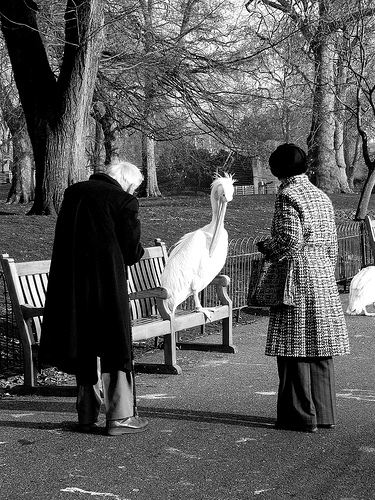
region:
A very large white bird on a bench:
[157, 173, 235, 323]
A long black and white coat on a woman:
[264, 176, 350, 356]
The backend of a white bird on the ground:
[344, 261, 374, 316]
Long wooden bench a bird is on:
[3, 237, 236, 384]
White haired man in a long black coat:
[45, 159, 150, 433]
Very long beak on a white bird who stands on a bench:
[205, 198, 226, 255]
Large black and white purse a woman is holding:
[247, 253, 298, 310]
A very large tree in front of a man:
[8, 55, 100, 214]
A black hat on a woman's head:
[268, 139, 308, 179]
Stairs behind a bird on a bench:
[225, 146, 255, 186]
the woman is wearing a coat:
[240, 146, 340, 413]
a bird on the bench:
[161, 178, 244, 326]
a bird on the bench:
[125, 182, 255, 381]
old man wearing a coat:
[56, 160, 161, 380]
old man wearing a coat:
[43, 181, 208, 430]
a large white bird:
[156, 167, 262, 330]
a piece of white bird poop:
[231, 430, 257, 443]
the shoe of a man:
[106, 414, 151, 436]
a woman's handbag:
[248, 239, 298, 307]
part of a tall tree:
[258, 1, 372, 195]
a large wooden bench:
[3, 233, 237, 406]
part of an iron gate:
[335, 215, 369, 279]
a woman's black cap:
[267, 137, 310, 182]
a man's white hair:
[106, 157, 147, 195]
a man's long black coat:
[31, 167, 147, 377]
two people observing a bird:
[37, 143, 349, 437]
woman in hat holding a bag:
[245, 143, 352, 432]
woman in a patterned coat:
[250, 141, 350, 432]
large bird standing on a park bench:
[151, 171, 240, 374]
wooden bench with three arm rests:
[2, 235, 237, 386]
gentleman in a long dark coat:
[36, 160, 149, 436]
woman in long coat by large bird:
[161, 142, 350, 433]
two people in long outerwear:
[37, 143, 350, 436]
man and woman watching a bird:
[35, 141, 350, 436]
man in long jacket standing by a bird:
[35, 160, 239, 434]